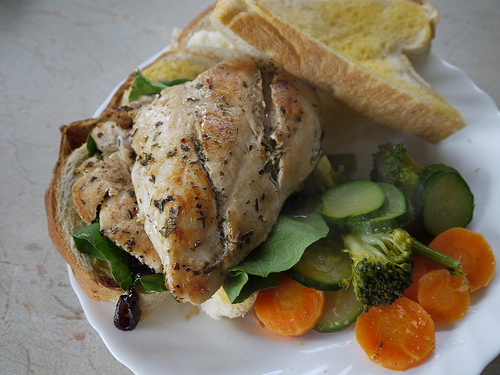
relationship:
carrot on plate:
[426, 209, 488, 274] [45, 58, 464, 363]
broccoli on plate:
[341, 232, 424, 316] [45, 58, 464, 363]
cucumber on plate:
[399, 153, 471, 233] [45, 58, 464, 363]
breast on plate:
[162, 99, 300, 237] [45, 58, 464, 363]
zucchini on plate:
[90, 222, 151, 289] [45, 58, 464, 363]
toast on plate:
[305, 14, 408, 105] [45, 58, 464, 363]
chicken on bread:
[175, 121, 297, 211] [309, 44, 422, 148]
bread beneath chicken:
[309, 44, 422, 148] [175, 121, 297, 211]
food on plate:
[39, 3, 499, 363] [45, 58, 464, 363]